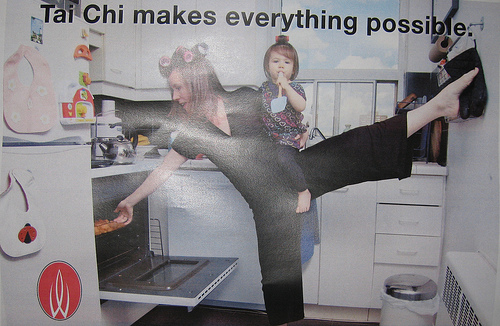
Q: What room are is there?
A: Kitchen.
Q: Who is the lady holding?
A: Baby.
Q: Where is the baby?
A: Lady's hip.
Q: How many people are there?
A: Two.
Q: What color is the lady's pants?
A: Black.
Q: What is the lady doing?
A: Cooking.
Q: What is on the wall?
A: Lady's foot.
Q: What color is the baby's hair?
A: Brown.